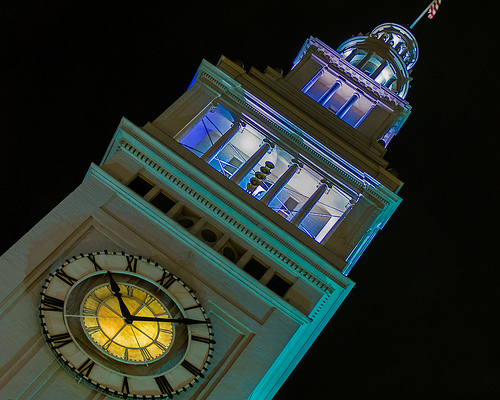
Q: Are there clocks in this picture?
A: Yes, there is a clock.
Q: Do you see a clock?
A: Yes, there is a clock.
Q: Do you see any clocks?
A: Yes, there is a clock.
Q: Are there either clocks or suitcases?
A: Yes, there is a clock.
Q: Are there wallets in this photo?
A: No, there are no wallets.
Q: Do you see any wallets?
A: No, there are no wallets.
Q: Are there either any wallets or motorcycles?
A: No, there are no wallets or motorcycles.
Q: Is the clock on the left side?
A: Yes, the clock is on the left of the image.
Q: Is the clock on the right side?
A: No, the clock is on the left of the image.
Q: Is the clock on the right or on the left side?
A: The clock is on the left of the image.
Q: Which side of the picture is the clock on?
A: The clock is on the left of the image.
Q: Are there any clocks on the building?
A: Yes, there is a clock on the building.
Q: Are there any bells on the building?
A: No, there is a clock on the building.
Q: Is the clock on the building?
A: Yes, the clock is on the building.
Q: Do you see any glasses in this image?
A: No, there are no glasses.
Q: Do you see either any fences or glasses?
A: No, there are no glasses or fences.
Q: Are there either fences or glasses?
A: No, there are no glasses or fences.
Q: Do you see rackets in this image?
A: No, there are no rackets.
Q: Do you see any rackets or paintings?
A: No, there are no rackets or paintings.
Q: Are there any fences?
A: No, there are no fences.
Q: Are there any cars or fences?
A: No, there are no fences or cars.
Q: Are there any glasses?
A: No, there are no glasses.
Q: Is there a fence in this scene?
A: No, there are no fences.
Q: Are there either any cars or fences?
A: No, there are no fences or cars.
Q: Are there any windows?
A: Yes, there are windows.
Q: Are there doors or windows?
A: Yes, there are windows.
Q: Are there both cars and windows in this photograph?
A: No, there are windows but no cars.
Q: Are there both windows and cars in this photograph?
A: No, there are windows but no cars.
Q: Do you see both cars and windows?
A: No, there are windows but no cars.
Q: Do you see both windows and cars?
A: No, there are windows but no cars.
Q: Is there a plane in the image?
A: No, there are no airplanes.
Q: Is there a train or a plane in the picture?
A: No, there are no airplanes or trains.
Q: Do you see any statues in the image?
A: No, there are no statues.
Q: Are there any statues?
A: No, there are no statues.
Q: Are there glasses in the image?
A: No, there are no glasses.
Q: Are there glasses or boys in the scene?
A: No, there are no glasses or boys.